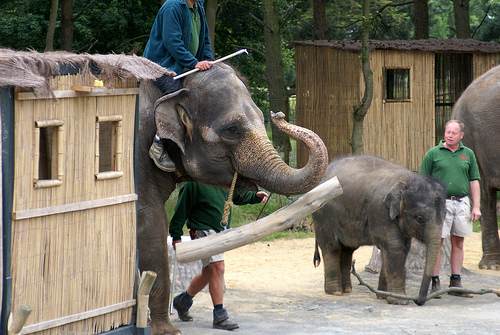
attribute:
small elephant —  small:
[309, 153, 447, 305]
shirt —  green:
[415, 138, 480, 203]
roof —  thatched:
[283, 37, 499, 58]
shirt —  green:
[416, 138, 480, 195]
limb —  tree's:
[334, 272, 497, 307]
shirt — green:
[410, 129, 484, 197]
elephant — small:
[56, 65, 331, 281]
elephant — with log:
[276, 110, 451, 321]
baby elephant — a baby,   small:
[315, 155, 446, 305]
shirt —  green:
[422, 139, 479, 200]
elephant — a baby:
[308, 156, 449, 307]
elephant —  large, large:
[128, 62, 330, 332]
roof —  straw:
[287, 32, 490, 47]